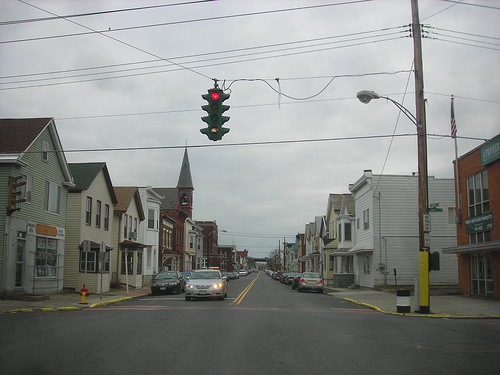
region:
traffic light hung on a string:
[190, 72, 237, 148]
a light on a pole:
[341, 80, 441, 315]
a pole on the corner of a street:
[401, 3, 441, 321]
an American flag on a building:
[444, 87, 466, 210]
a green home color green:
[8, 111, 73, 301]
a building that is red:
[446, 131, 499, 302]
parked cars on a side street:
[258, 259, 333, 298]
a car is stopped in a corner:
[172, 263, 240, 305]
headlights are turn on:
[179, 279, 224, 295]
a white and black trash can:
[388, 283, 420, 318]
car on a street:
[178, 265, 232, 305]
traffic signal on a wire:
[196, 73, 241, 151]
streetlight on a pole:
[348, 83, 435, 140]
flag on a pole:
[438, 87, 465, 149]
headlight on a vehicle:
[211, 280, 228, 295]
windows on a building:
[82, 191, 116, 234]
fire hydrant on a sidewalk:
[76, 280, 93, 315]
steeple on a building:
[171, 135, 201, 194]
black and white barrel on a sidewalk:
[388, 283, 418, 320]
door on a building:
[9, 226, 31, 299]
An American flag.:
[437, 93, 462, 208]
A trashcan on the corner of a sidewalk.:
[391, 284, 422, 322]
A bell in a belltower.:
[177, 182, 197, 208]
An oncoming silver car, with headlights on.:
[181, 260, 232, 312]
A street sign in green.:
[422, 192, 449, 221]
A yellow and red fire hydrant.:
[75, 281, 97, 311]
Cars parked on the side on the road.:
[260, 260, 330, 300]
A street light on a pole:
[354, 75, 438, 172]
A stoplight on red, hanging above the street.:
[177, 69, 241, 153]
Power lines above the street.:
[2, 4, 497, 142]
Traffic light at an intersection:
[196, 76, 238, 153]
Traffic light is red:
[191, 75, 253, 152]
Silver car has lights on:
[177, 259, 244, 313]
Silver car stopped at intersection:
[180, 257, 257, 322]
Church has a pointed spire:
[172, 133, 204, 215]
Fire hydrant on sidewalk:
[66, 277, 100, 312]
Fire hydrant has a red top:
[71, 278, 100, 316]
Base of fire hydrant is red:
[71, 282, 93, 307]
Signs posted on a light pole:
[408, 203, 443, 253]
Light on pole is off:
[355, 77, 430, 153]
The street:
[106, 291, 180, 371]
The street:
[270, 366, 282, 373]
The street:
[282, 318, 340, 372]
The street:
[306, 291, 332, 336]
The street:
[251, 267, 403, 368]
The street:
[214, 318, 353, 374]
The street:
[242, 307, 323, 362]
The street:
[255, 333, 300, 370]